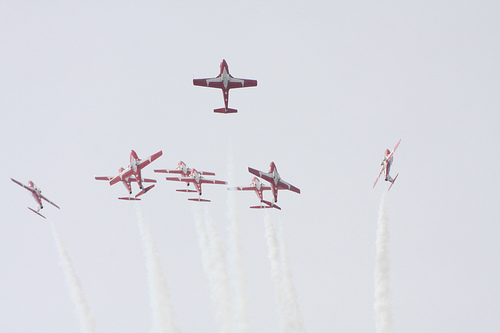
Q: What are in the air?
A: Planes.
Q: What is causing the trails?
A: Smoke from plane.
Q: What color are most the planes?
A: Red.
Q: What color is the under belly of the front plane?
A: White.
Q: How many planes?
A: Nine.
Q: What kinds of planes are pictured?
A: Jet planes.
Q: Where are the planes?
A: In the air.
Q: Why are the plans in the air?
A: Flying.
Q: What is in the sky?
A: A group of planes.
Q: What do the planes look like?
A: Red and white.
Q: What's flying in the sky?
A: Planes.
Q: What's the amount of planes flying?
A: Nine.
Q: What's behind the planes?
A: Smoke trails.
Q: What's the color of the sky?
A: Grey.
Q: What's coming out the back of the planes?
A: Smoke trails.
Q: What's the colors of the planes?
A: Red and white.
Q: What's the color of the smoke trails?
A: White.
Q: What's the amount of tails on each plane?
A: One.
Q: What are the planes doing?
A: Performing a stunt.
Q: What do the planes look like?
A: Red and white.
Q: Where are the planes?
A: In the sky.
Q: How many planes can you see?
A: Nine.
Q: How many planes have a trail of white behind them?
A: Nine.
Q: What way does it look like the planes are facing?
A: Up.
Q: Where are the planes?
A: In the sky.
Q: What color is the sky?
A: White.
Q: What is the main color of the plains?
A: Red.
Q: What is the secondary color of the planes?
A: White.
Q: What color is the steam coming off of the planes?
A: White.